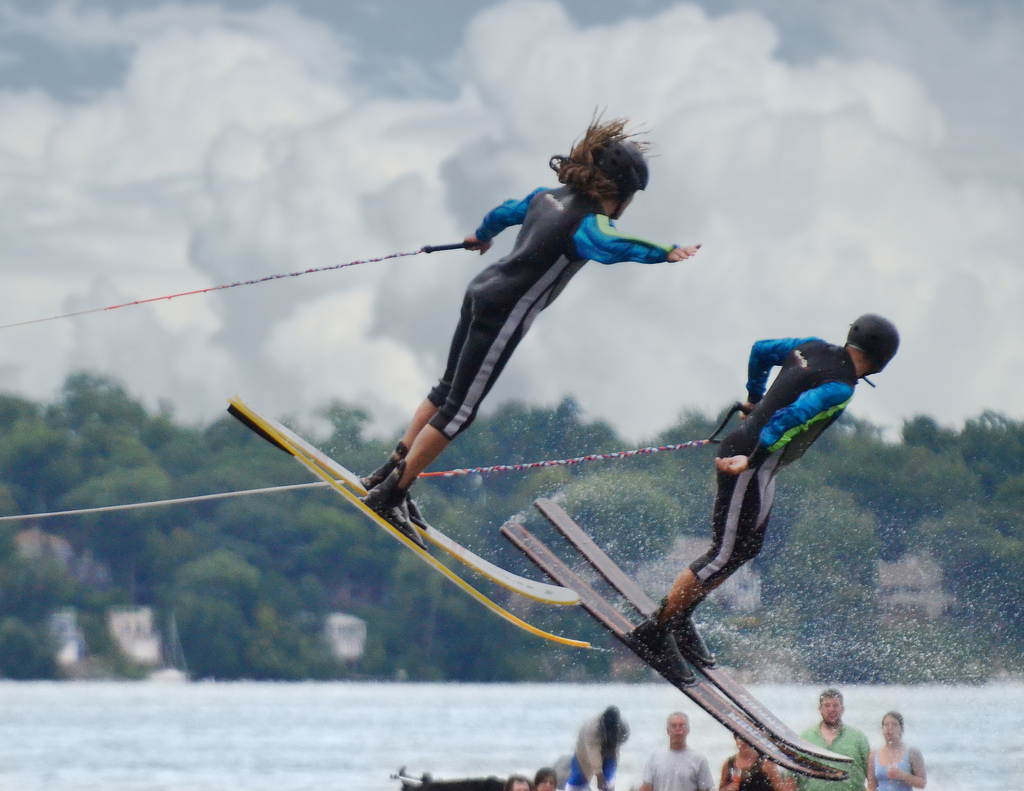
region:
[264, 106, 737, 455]
young woman doing trick on water ski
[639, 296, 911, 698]
young man doing trick on water ski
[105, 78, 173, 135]
white clouds in blue sky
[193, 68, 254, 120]
white clouds in blue sky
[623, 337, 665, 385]
white clouds in blue sky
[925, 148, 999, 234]
white clouds in blue sky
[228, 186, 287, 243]
white clouds in blue sky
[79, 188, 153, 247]
white clouds in blue sky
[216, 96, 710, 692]
a person in the air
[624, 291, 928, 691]
a person in the air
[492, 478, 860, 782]
two skies on the air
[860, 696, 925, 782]
woman has purple top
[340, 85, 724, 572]
person with black hair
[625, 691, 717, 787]
a man looking up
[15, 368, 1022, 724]
trees on the background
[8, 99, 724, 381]
a rope on the left hand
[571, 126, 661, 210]
person wearing a black helmet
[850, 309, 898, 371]
person wearing a black helmet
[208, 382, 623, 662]
Person on water skis in the air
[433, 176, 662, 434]
Person wearing a black and blue wet suit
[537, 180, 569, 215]
white letters on the suit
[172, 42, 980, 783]
two people are in the air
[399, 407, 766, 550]
this section of the cord is colorful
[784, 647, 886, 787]
a man in a green polo shirt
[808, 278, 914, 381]
this is a black helmet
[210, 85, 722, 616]
her right arm is extended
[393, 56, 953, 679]
they are wearing matching wetsuits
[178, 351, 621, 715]
these water skis are yellow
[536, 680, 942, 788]
these are spectators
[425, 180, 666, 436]
a black and blue ski suit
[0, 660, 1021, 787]
a body of water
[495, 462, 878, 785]
pair of water skis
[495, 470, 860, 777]
pair of water skis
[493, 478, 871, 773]
pair of water skis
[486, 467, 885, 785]
pair of water skis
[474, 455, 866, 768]
pair of water skis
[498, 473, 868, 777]
pair of water skis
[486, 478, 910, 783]
pair of water skis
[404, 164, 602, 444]
woman wearing a wetsuit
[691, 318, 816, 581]
man wearing a wetsuit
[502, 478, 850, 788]
man on black skis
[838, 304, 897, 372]
man wearing a black helmet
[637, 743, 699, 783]
man wearing a white shirt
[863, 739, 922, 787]
woman wearing a blue shirt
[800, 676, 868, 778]
man wearing green shirt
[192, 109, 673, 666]
skier with long hair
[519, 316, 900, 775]
skier wearing hair cap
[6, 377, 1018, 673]
trees behind the lake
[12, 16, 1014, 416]
white clouds above the trees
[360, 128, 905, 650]
skiers weraing black, blue and grey wetsuits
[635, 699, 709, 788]
man wearing white shirt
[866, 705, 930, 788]
woman wearing tank top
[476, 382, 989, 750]
water spray coming from the skiers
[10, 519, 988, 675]
buildings among the trees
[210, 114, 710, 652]
a woman on skies in the air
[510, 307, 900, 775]
a man on skies in the air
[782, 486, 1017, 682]
water droplets in the air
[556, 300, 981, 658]
a man on skies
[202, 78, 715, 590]
a lady on skies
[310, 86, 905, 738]
People on water skis